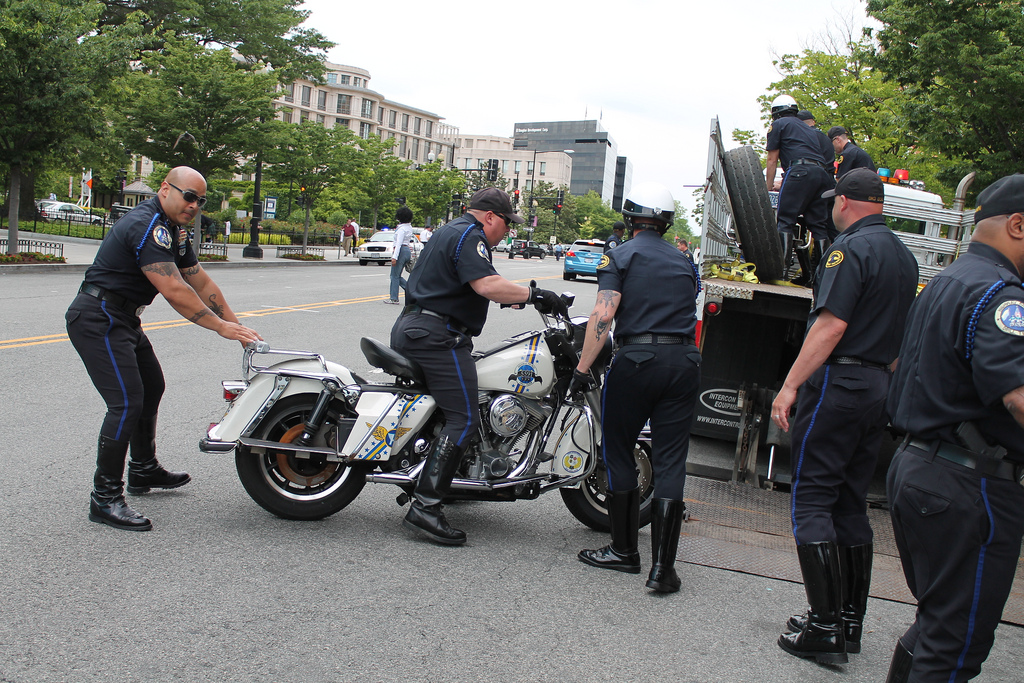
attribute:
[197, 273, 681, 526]
motorcycle — white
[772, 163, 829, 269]
pants — blue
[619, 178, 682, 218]
helmet — white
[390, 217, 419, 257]
shirt — white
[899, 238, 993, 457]
shirt — blue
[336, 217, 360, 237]
shirt — red